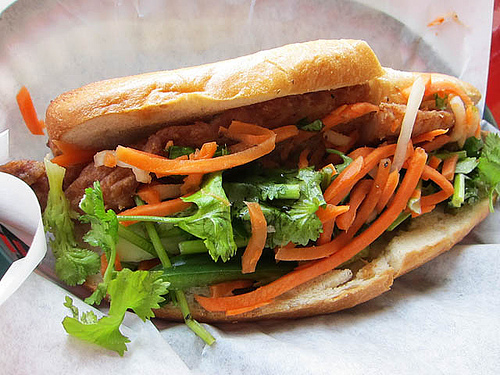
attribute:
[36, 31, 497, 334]
sandwich — overflowing, vegetarian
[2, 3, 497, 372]
paper — wax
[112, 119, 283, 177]
carrot — long, orange, thinly, hand chopped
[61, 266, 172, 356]
lettuce — light green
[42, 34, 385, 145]
bun — thick, bread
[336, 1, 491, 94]
paper — wax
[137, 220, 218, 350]
stick — thin, green, food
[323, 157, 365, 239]
carrot — orange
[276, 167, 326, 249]
lettuce — green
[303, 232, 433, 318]
bread — torn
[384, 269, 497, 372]
paper — white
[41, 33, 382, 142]
bread — brown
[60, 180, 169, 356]
parsley — green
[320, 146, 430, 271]
carrot — shredded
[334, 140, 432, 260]
carrot — orange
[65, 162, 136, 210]
meat — brown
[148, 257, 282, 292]
pepper — green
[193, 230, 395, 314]
carrot — thinly, hand chopped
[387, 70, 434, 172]
onion — shredded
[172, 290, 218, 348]
stem — bent, vegetable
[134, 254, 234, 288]
bell pepper — green , slice 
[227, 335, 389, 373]
paper — white wax deli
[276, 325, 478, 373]
paper — white wax deli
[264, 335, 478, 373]
paper — white wax deli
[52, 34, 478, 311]
roll — nice sourdough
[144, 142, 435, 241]
vegetables — middle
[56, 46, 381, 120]
sandwich — toasted bread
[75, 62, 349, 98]
bread — toasted , light brown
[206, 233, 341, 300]
carrots — sliced 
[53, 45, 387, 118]
bread — light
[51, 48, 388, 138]
bread — toasted, white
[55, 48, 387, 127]
bread — vegetables inside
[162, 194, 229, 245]
lettuce — green